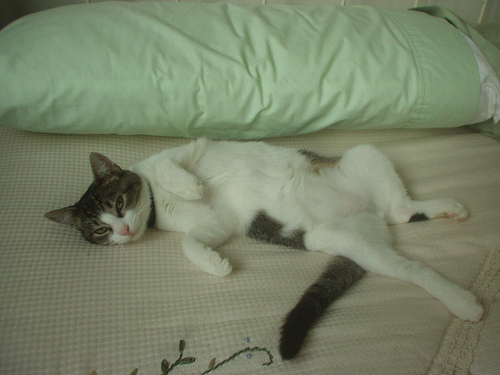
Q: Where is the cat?
A: On the bed.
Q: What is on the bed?
A: The cat.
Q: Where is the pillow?
A: Behind the cat.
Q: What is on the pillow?
A: A green pillow case.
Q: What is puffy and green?
A: Pillow.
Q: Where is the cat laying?
A: On the bed.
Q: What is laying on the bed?
A: Cat.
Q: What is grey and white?
A: Cat.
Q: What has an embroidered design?
A: Blanket.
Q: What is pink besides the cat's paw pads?
A: Nose.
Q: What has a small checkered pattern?
A: Blanket.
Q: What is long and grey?
A: Cat's tail.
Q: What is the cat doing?
A: Laying on it's back.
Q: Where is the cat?
A: On a bed.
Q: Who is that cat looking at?
A: The viewer.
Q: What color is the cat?
A: White and grey.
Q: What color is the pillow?
A: Green.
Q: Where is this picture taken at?
A: In a bedroom.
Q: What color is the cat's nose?
A: Pink.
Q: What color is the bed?
A: White.